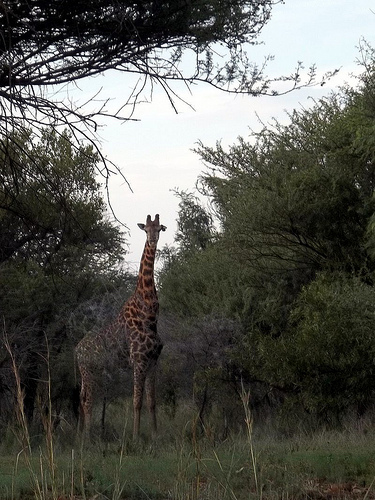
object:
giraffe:
[74, 214, 168, 441]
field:
[2, 403, 373, 500]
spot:
[144, 278, 153, 288]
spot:
[136, 310, 146, 320]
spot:
[144, 259, 152, 268]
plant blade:
[239, 375, 259, 495]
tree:
[154, 35, 375, 432]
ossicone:
[155, 214, 159, 220]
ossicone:
[146, 215, 151, 221]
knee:
[136, 402, 142, 410]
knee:
[150, 401, 155, 410]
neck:
[138, 243, 157, 289]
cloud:
[137, 137, 169, 213]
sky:
[271, 4, 374, 52]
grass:
[0, 335, 260, 500]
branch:
[0, 0, 343, 230]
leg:
[133, 368, 145, 435]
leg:
[147, 384, 157, 436]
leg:
[80, 384, 93, 430]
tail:
[73, 350, 80, 422]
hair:
[72, 384, 80, 422]